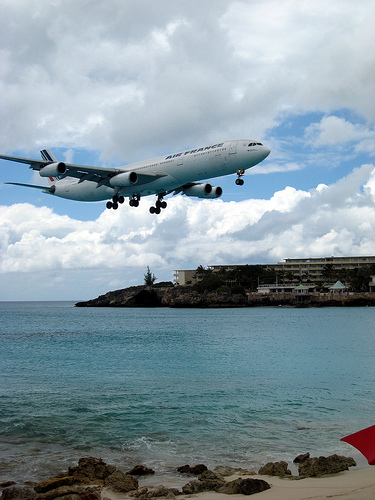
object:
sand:
[212, 467, 375, 500]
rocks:
[103, 300, 107, 303]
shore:
[157, 285, 310, 328]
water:
[9, 322, 173, 421]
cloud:
[167, 24, 222, 54]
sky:
[270, 0, 374, 255]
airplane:
[0, 138, 271, 215]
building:
[196, 257, 324, 293]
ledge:
[152, 298, 297, 319]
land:
[77, 249, 375, 306]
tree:
[143, 264, 157, 285]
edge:
[27, 276, 170, 312]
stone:
[227, 477, 271, 495]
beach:
[0, 436, 357, 499]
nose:
[246, 137, 269, 157]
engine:
[109, 167, 138, 189]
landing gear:
[235, 171, 245, 186]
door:
[228, 141, 237, 156]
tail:
[37, 182, 73, 202]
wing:
[0, 152, 156, 186]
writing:
[206, 144, 223, 150]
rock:
[177, 462, 205, 477]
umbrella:
[341, 418, 375, 469]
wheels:
[161, 201, 167, 209]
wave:
[21, 400, 176, 451]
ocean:
[0, 311, 269, 444]